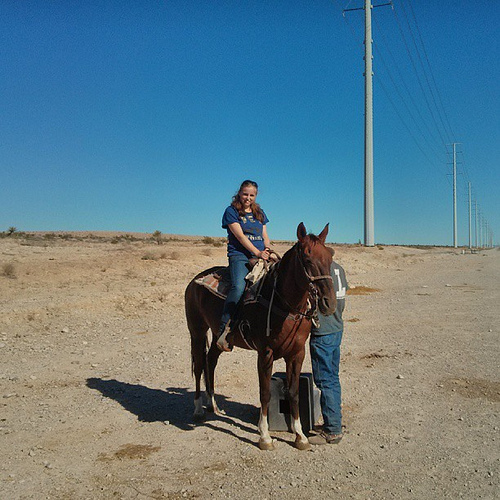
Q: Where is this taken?
A: The desert.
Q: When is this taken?
A: Daytime.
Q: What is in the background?
A: Powerlines.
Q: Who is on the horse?
A: The woman.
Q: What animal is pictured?
A: A horse.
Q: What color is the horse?
A: Brown.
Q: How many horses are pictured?
A: One.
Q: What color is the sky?
A: Blue.